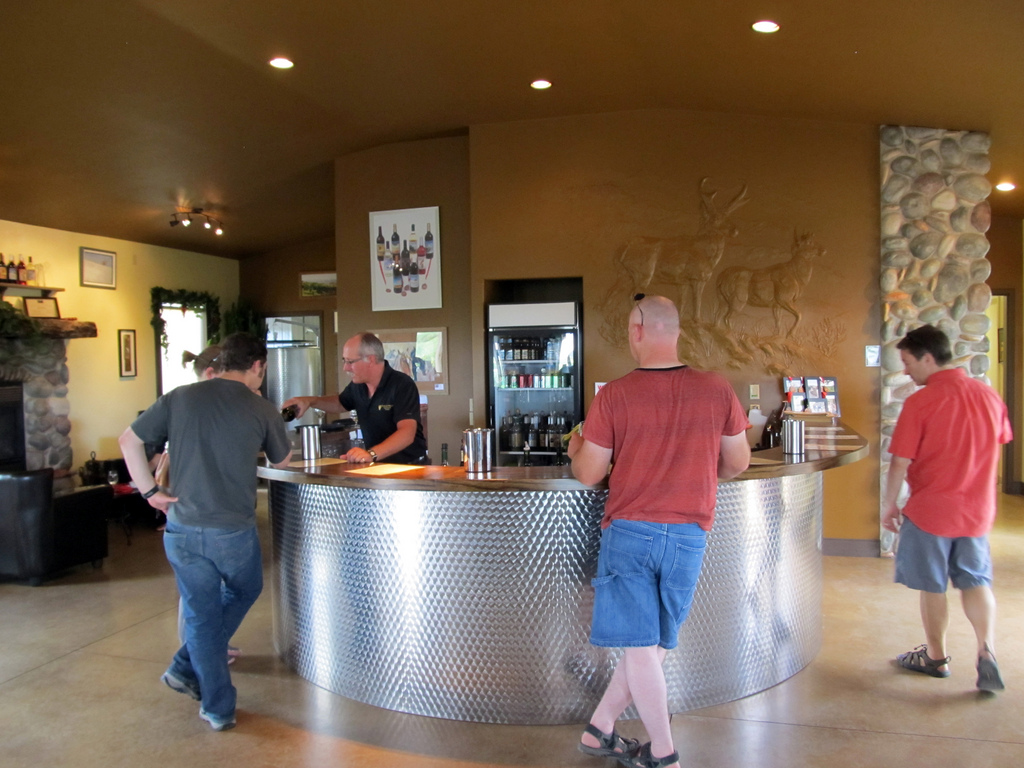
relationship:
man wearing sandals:
[560, 286, 745, 762] [581, 716, 693, 766]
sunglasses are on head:
[633, 281, 665, 326] [621, 286, 694, 372]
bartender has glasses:
[288, 324, 433, 473] [343, 352, 389, 374]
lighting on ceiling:
[261, 43, 303, 81] [12, 6, 1023, 236]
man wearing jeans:
[113, 321, 302, 751] [154, 508, 272, 748]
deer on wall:
[605, 174, 848, 358] [450, 109, 886, 523]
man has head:
[560, 286, 745, 762] [621, 286, 694, 372]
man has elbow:
[560, 286, 745, 762] [563, 459, 609, 496]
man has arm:
[560, 286, 745, 762] [563, 390, 617, 491]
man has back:
[560, 286, 745, 762] [608, 446, 713, 519]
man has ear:
[560, 286, 745, 762] [630, 316, 651, 346]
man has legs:
[560, 286, 745, 762] [568, 508, 721, 765]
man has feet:
[560, 286, 745, 762] [584, 717, 688, 755]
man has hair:
[113, 321, 302, 751] [216, 339, 274, 374]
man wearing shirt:
[113, 321, 302, 751] [133, 377, 288, 532]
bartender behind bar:
[288, 324, 433, 473] [271, 382, 873, 713]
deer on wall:
[605, 174, 848, 358] [875, 123, 1000, 585]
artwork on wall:
[354, 197, 458, 317] [450, 109, 886, 523]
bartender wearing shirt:
[288, 324, 433, 473] [351, 363, 428, 465]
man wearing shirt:
[560, 286, 745, 762] [570, 360, 744, 529]